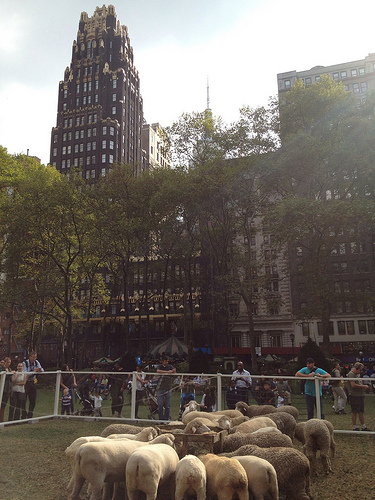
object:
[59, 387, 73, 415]
child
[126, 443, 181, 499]
sheep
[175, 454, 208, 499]
sheep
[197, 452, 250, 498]
sheep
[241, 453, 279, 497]
sheep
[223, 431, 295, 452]
sheep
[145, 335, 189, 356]
awning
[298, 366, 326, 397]
shirt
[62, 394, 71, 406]
shirt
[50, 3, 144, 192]
building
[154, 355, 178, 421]
person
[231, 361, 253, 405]
person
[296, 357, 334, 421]
person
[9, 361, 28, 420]
person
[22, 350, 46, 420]
person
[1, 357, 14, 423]
person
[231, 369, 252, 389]
shirt